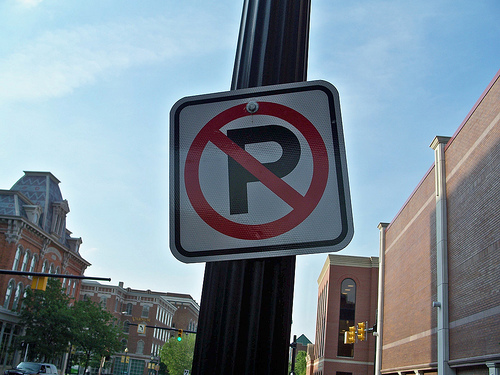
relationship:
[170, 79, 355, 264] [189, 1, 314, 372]
sign on pole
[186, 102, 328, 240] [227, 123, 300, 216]
circle around letter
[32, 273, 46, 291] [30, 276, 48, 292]
back of traffic light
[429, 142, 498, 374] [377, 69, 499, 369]
shadow on brick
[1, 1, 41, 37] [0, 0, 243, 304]
cloud in sky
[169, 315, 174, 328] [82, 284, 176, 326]
window on floor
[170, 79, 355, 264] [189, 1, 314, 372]
sign attached to pole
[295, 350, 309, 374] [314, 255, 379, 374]
tree in front of building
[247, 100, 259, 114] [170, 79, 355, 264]
screw securing sign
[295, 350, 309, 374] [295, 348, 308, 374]
tree with leaves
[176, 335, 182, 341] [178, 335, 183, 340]
light signaling green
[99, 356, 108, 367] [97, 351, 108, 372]
flag hanging on pole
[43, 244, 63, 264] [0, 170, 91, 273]
design on roof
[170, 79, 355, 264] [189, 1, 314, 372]
sign on a pole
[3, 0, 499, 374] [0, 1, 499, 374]
daytime in city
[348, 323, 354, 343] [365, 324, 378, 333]
light on pole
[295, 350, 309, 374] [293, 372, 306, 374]
tree on curb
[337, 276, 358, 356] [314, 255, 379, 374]
window on building